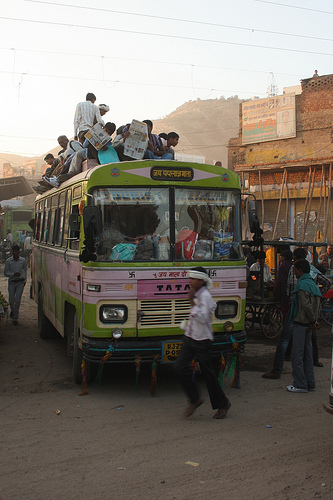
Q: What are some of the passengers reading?
A: Newspapers.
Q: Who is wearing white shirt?
A: The man.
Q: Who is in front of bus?
A: Man in white.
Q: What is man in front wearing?
A: White shirt.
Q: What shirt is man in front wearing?
A: A white one.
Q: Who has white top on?
A: Man in front.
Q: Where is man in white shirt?
A: In front of bus.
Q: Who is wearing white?
A: Man in blue jeans.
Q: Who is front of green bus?
A: Man in white.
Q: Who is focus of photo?
A: Man in white.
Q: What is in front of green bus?
A: Windshield.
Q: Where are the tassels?
A: Hanging from front bumper of bus.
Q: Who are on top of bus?
A: Group of people.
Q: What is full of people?
A: A bus is packed full of people.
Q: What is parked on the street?
A: A large green bus.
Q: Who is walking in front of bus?
A: A man in the street.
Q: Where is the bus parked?
A: On unpaved dirt road.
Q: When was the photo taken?
A: Daytime.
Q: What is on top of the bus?
A: People.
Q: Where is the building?
A: Right side of the bus.